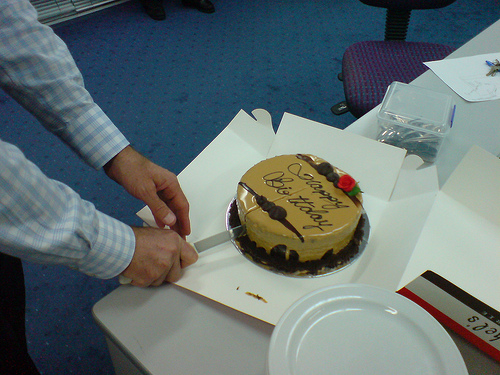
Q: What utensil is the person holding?
A: Knife.